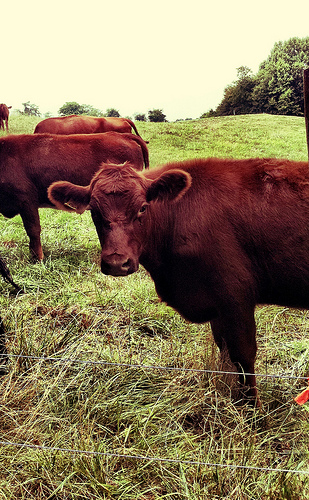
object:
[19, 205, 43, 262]
leg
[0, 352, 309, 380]
barbed wire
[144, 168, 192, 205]
ear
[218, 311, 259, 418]
leg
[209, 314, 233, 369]
leg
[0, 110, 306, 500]
grass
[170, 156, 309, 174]
back fur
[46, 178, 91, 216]
ear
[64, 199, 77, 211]
tag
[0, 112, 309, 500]
ground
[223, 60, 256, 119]
trees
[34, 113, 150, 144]
cow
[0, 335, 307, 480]
fence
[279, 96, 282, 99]
leaves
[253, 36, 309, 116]
green trees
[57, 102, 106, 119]
green trees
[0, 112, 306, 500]
hill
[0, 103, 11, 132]
cow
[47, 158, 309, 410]
cow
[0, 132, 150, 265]
cow